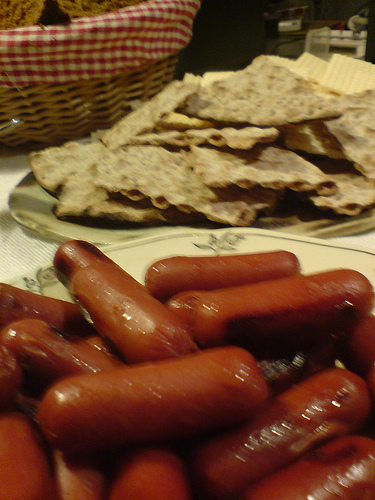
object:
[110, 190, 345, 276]
plate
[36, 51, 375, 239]
chips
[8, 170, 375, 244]
platter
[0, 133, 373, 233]
plate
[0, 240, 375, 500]
hot dogs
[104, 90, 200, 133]
wall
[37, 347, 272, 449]
sausage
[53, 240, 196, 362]
sausage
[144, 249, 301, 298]
sausage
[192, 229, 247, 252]
flower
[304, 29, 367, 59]
chair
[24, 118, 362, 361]
plate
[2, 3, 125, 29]
bread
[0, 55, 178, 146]
basket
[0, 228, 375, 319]
platter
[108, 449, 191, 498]
sausage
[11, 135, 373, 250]
plate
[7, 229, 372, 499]
plate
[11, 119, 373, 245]
plate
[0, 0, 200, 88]
cloth